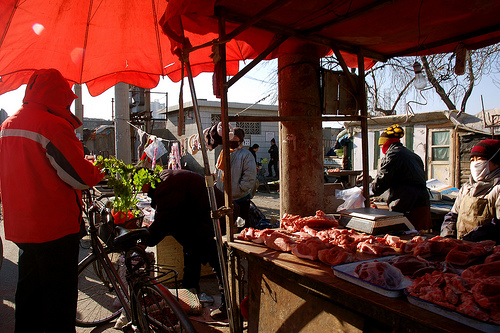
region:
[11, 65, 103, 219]
a man wearing a orange jacket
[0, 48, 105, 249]
a man wearing a hooded jacket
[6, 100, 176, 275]
a man holding a bike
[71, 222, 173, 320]
the front wheel on a bike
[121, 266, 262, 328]
the back wheel on a bike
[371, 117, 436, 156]
a man wearing a hat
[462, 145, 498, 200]
a woman wearing a hat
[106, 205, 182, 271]
a seat on a bike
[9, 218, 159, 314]
a man wearing pants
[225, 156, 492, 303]
meat on a table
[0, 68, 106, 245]
a bright orange jacket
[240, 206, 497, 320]
a display of meats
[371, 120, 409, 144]
a yellow and black hat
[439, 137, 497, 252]
a woman wearing a face mask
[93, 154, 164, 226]
a few potted plants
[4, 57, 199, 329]
a man with a bicycle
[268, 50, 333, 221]
a rust covered post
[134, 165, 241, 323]
a man dressed in black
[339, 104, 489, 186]
a run down structure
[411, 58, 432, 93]
a single light bulb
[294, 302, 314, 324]
part of a shade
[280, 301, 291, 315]
part of a board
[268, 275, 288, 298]
part of a board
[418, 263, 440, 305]
aprt of a meat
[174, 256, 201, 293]
part of a basket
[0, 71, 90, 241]
the jacket is red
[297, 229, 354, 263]
the meat is raw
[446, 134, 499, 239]
the woman is wearing mask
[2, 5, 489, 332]
the scene is outdoors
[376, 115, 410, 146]
the marvin is yellow and black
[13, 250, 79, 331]
the pants are black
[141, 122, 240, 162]
clothes are on the hanging line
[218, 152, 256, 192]
the jacket is silver in color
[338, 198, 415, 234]
the scale is on the table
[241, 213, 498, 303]
the meat is red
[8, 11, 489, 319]
People at outdoor food market.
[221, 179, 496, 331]
Slaughterd meat on sale at an outdoor marketplace.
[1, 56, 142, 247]
Man wearing a hooded orange gray and black jacket.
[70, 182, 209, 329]
Bicycle that has a black seat.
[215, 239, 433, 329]
Wooden display counter at an outdoor marketplace.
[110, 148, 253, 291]
Man bending down fixing the plats at his vendor's stand.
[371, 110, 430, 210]
Female vendor wearing a orange and green hat.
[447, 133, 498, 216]
Female vendor wearing a face mask to protect her from inhaling the fumes from the slaughtered animal meat.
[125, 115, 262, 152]
Socks hanging from a clothesline at an outdoor marketplace.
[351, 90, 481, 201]
Trailer home in the backdrop of an outdoor marketplace.